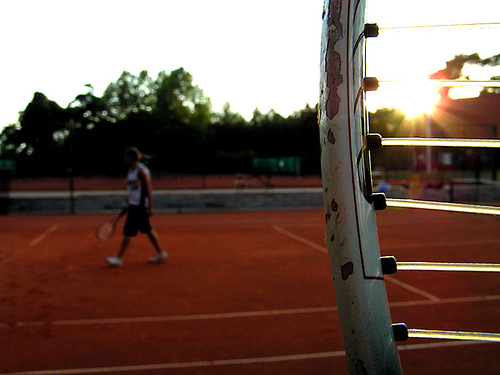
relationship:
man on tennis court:
[107, 147, 169, 268] [0, 175, 499, 375]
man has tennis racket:
[107, 147, 169, 268] [96, 205, 128, 241]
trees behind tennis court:
[1, 56, 498, 173] [0, 175, 499, 375]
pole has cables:
[318, 0, 404, 374] [364, 21, 499, 373]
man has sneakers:
[107, 147, 169, 268] [105, 251, 169, 265]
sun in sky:
[397, 82, 441, 119] [1, 0, 499, 129]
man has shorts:
[107, 147, 169, 268] [122, 206, 153, 237]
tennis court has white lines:
[0, 175, 499, 375] [0, 304, 345, 373]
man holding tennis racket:
[107, 147, 169, 268] [96, 205, 128, 241]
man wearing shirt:
[107, 147, 169, 268] [125, 163, 152, 205]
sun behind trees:
[397, 82, 441, 119] [1, 56, 498, 173]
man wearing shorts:
[107, 147, 169, 268] [122, 206, 153, 237]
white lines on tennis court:
[0, 304, 345, 373] [0, 175, 499, 375]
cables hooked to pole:
[364, 21, 499, 373] [318, 0, 404, 374]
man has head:
[107, 147, 169, 268] [122, 147, 141, 167]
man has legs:
[107, 147, 169, 268] [114, 229, 163, 256]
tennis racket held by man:
[96, 205, 128, 241] [107, 147, 169, 268]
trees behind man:
[1, 56, 498, 173] [107, 147, 169, 268]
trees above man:
[1, 56, 498, 173] [107, 147, 169, 268]